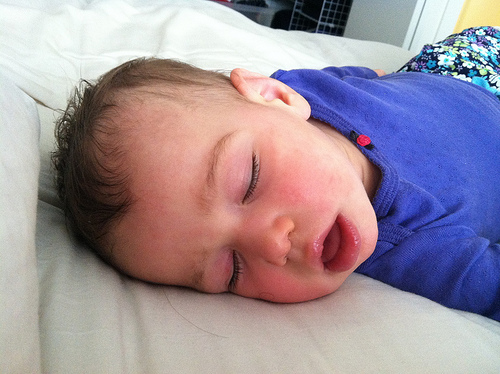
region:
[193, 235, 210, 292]
The left eyebrow of the baby.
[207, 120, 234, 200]
The right eyebrow of the baby.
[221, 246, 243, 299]
The left eye of the baby.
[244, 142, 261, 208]
The right eye of the baby.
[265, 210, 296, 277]
The nose and nostril of the baby.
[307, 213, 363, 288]
The open mouth of the baby.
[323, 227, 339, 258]
The tongue of the baby.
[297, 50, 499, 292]
The blue shirt the baby is wearing.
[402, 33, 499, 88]
The floral patterned bottoms the baby is wearing.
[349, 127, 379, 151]
The red dot on the baby's shirt collar.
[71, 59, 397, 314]
baby with mouth open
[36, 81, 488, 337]
baby laying down on bed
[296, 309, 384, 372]
white sheet under baby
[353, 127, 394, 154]
red thing on baby's shirt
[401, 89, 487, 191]
blue shirt of kid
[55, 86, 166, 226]
brown hair on kid's head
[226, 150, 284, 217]
eye of the kid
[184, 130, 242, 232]
eyebrow of the kid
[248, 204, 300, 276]
nose of the kid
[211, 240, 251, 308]
right eye of kid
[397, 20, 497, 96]
flowered pants on a baby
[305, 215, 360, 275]
an open mouth on a baby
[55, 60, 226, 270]
dark hair on a baby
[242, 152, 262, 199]
dark eyelashes on a baby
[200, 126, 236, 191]
brown eyebrow on a baby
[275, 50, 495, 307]
blue shirt on a baby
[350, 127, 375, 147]
a pink rosette on a blue shirt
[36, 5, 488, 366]
white sheets on a bed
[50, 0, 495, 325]
a baby sleeping on a bed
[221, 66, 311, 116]
an ear on a baby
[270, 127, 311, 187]
black spots on baby's face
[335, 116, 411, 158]
red flower on blue shirt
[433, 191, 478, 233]
wrinkles in blue shirt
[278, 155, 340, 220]
baby's rosy red cheeks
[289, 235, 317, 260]
groove in baby's upper lip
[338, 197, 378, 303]
large red lip on baby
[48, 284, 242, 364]
baby laying on white sheet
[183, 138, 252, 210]
baby's bushy black eyebrows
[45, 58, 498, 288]
baby sleeping on white sheet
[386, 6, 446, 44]
edge of white wall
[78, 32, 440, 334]
baby sleeping on bed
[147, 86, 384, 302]
kid with mouth open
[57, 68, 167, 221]
hair on kid's head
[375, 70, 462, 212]
blue shirt on kid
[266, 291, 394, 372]
white sheet under kid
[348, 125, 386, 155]
red part of kid's shirt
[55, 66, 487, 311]
kid laying on back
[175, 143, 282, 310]
eyes of the kid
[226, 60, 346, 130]
ear of the kid